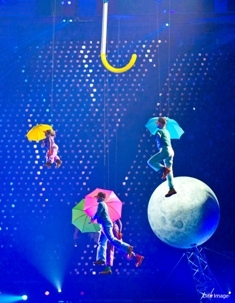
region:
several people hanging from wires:
[25, 109, 199, 279]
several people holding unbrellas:
[18, 107, 183, 277]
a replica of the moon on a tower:
[147, 172, 218, 256]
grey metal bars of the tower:
[185, 246, 219, 301]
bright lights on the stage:
[10, 278, 73, 301]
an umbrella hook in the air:
[85, 0, 144, 82]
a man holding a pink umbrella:
[77, 186, 130, 256]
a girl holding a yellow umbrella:
[28, 117, 65, 167]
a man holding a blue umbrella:
[141, 105, 189, 197]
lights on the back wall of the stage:
[65, 60, 104, 146]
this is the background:
[11, 214, 35, 249]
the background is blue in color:
[27, 265, 40, 272]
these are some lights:
[6, 282, 56, 300]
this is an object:
[143, 176, 220, 262]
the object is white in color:
[162, 217, 198, 238]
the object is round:
[144, 179, 215, 249]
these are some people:
[14, 114, 173, 272]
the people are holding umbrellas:
[26, 102, 181, 213]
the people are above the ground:
[17, 94, 191, 273]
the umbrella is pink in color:
[110, 196, 121, 217]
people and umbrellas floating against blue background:
[4, 4, 223, 284]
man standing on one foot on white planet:
[142, 109, 217, 244]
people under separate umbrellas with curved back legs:
[69, 185, 140, 272]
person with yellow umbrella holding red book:
[23, 119, 58, 165]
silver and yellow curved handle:
[96, 0, 133, 70]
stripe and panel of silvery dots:
[3, 36, 204, 270]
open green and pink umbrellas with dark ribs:
[68, 183, 119, 229]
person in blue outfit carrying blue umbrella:
[143, 113, 180, 185]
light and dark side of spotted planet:
[146, 175, 217, 245]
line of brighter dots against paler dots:
[55, 40, 97, 110]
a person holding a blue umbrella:
[143, 111, 183, 194]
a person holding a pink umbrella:
[85, 189, 129, 258]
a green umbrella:
[70, 199, 99, 235]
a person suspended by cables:
[147, 54, 186, 198]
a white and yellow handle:
[95, 39, 146, 85]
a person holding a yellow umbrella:
[29, 124, 68, 168]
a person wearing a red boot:
[134, 252, 144, 267]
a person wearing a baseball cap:
[92, 191, 106, 204]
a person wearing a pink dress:
[41, 129, 65, 172]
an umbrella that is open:
[146, 111, 185, 139]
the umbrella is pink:
[79, 184, 131, 238]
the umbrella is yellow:
[22, 116, 64, 155]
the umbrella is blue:
[136, 108, 184, 143]